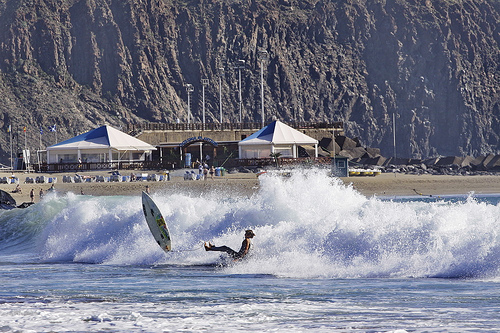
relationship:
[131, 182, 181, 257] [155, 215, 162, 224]
board has stickers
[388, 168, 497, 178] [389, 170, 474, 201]
rocks on beach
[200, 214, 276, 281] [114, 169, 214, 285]
person fell off board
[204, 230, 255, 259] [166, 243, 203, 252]
person wearing leg leash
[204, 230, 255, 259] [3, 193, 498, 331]
person in water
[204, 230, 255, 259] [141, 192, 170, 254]
person fallen off board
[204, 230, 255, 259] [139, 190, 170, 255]
person falling from board